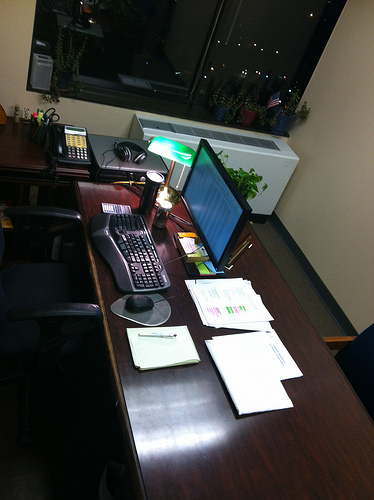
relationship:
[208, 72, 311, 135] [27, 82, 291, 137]
row on windowsill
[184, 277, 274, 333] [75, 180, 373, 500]
stack on desk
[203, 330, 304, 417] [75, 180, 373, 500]
stack on desk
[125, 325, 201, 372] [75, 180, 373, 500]
stack on desk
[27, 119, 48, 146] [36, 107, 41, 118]
cup holds pen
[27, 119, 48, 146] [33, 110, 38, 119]
cup holds highlighter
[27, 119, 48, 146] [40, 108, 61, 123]
cup holds scissors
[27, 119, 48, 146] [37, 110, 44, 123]
cup holds highlighter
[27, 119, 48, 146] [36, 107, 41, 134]
cup holds pen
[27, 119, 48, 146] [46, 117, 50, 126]
cup holds pen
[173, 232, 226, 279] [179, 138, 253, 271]
tray under monitor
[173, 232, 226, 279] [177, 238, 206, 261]
tray holds business card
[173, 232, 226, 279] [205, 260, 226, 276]
tray holds sticky note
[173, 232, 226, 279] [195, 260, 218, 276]
tray holds sticky note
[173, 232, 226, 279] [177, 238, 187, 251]
tray holds business card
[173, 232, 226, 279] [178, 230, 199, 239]
tray holds sticky note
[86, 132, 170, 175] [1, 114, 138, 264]
computer sitting on desk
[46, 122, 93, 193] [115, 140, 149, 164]
telephone beside headphone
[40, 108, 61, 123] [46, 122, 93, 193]
scissors beside telephone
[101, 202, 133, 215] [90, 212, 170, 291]
calculator beside keyboard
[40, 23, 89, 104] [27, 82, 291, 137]
plant on windowsill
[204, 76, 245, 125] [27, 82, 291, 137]
plant on windowsill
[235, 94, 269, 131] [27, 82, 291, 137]
plant on windowsill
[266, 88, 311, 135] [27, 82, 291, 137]
plant on windowsill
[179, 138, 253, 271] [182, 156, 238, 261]
monitor has spreadsheet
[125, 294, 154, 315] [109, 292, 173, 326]
computer mouse on mouse pad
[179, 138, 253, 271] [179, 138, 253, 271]
monitor has monitor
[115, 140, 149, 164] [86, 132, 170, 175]
headphone on computer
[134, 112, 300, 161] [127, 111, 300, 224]
top on air conditioning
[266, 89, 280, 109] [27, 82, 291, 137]
flag on windowsill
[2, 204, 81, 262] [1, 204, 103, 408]
arm on computer chair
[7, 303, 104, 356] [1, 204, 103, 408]
arm on computer chair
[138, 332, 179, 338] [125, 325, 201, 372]
pen on stack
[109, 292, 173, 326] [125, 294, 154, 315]
mouse pad beneath computer mouse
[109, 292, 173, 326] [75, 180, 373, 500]
mouse pad on desk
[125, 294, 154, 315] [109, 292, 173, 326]
computer mouse on top of mouse pad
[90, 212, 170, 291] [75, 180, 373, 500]
keyboard on desk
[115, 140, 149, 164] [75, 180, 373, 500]
headphone left of desk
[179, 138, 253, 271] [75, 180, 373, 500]
monitor on desk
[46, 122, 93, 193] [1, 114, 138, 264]
telephone on desk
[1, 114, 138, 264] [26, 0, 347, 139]
desk close to window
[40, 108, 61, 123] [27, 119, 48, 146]
scissors in cup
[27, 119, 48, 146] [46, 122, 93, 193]
cup next to telephone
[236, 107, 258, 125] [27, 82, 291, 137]
plant pot on windowsill